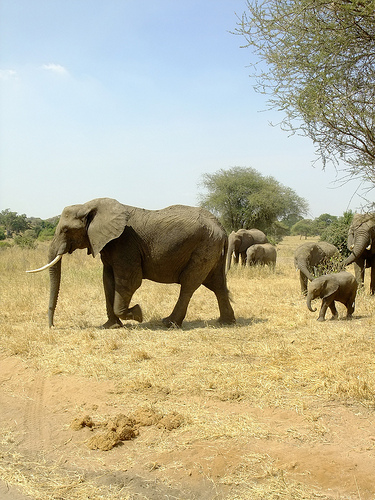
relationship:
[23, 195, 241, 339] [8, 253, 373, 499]
elephant on grass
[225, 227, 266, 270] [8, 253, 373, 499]
mother on grass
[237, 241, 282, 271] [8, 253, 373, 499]
elephant on grass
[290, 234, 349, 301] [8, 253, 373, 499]
elephant on grass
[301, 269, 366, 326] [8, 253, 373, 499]
elephant on grass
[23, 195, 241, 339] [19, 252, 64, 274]
elephant has tusks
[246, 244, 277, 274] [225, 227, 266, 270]
elephant has mother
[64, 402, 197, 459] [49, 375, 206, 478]
dunn on ground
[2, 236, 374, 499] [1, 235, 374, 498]
golden grass on ground